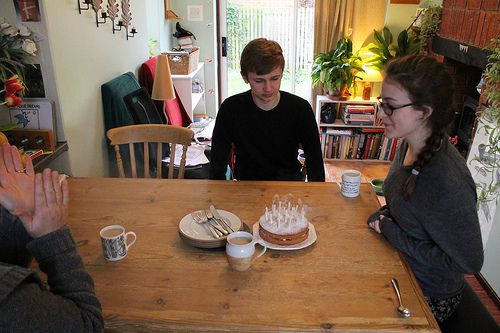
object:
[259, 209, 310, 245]
cake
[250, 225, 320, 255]
plate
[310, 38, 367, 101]
plant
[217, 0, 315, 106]
door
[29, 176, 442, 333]
table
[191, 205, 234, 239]
silverware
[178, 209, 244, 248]
plates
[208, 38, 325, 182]
man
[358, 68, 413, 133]
ground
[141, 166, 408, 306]
tires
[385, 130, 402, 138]
chin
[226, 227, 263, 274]
pitcher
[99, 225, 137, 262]
coffee.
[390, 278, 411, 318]
spoon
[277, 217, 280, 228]
candles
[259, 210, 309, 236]
top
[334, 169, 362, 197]
mug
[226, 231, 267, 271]
mug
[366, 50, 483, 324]
girl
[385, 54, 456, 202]
hair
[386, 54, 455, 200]
french braid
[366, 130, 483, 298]
shirt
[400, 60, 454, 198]
braid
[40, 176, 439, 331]
table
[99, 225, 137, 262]
cup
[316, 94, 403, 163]
shelf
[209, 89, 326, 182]
top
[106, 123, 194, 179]
chair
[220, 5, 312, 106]
sun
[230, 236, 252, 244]
cream